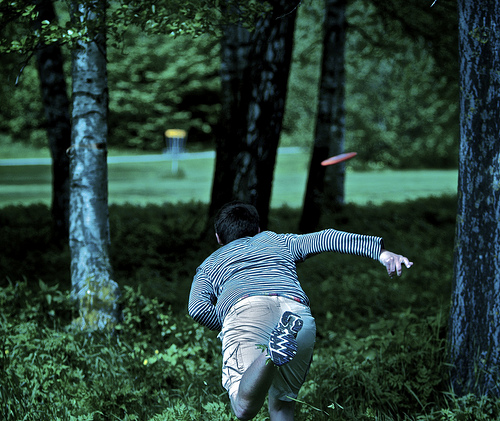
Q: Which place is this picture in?
A: It is at the field.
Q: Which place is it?
A: It is a field.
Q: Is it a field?
A: Yes, it is a field.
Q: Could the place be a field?
A: Yes, it is a field.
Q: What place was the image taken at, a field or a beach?
A: It was taken at a field.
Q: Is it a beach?
A: No, it is a field.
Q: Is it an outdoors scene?
A: Yes, it is outdoors.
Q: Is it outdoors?
A: Yes, it is outdoors.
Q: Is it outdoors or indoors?
A: It is outdoors.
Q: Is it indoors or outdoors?
A: It is outdoors.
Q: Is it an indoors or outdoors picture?
A: It is outdoors.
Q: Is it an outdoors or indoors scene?
A: It is outdoors.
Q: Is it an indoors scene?
A: No, it is outdoors.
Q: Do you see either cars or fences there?
A: No, there are no fences or cars.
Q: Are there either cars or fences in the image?
A: No, there are no fences or cars.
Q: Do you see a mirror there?
A: No, there are no mirrors.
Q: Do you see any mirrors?
A: No, there are no mirrors.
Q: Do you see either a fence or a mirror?
A: No, there are no mirrors or fences.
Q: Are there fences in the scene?
A: No, there are no fences.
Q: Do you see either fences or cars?
A: No, there are no fences or cars.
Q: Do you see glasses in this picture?
A: No, there are no glasses.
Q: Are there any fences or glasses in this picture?
A: No, there are no glasses or fences.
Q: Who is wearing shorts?
A: The man is wearing shorts.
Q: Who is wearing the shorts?
A: The man is wearing shorts.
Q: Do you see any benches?
A: No, there are no benches.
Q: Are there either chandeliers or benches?
A: No, there are no benches or chandeliers.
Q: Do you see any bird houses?
A: No, there are no bird houses.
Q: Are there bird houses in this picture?
A: No, there are no bird houses.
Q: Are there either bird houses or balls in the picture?
A: No, there are no bird houses or balls.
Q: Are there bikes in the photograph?
A: No, there are no bikes.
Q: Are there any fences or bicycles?
A: No, there are no bicycles or fences.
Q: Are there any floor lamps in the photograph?
A: No, there are no floor lamps.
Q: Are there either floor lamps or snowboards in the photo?
A: No, there are no floor lamps or snowboards.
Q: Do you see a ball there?
A: No, there are no balls.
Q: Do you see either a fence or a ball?
A: No, there are no balls or fences.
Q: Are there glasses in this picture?
A: No, there are no glasses.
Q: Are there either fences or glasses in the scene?
A: No, there are no glasses or fences.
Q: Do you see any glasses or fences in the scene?
A: No, there are no glasses or fences.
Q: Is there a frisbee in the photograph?
A: Yes, there is a frisbee.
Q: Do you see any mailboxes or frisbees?
A: Yes, there is a frisbee.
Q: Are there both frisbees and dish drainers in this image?
A: No, there is a frisbee but no dish drainers.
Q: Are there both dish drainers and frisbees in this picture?
A: No, there is a frisbee but no dish drainers.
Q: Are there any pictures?
A: No, there are no pictures.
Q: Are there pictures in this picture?
A: No, there are no pictures.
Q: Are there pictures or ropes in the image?
A: No, there are no pictures or ropes.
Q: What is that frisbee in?
A: The frisbee is in the air.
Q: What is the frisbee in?
A: The frisbee is in the air.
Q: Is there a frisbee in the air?
A: Yes, there is a frisbee in the air.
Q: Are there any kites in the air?
A: No, there is a frisbee in the air.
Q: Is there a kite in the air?
A: No, there is a frisbee in the air.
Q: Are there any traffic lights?
A: No, there are no traffic lights.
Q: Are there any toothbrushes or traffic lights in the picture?
A: No, there are no traffic lights or toothbrushes.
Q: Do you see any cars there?
A: No, there are no cars.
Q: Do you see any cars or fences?
A: No, there are no cars or fences.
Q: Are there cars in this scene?
A: No, there are no cars.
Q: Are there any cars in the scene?
A: No, there are no cars.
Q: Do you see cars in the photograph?
A: No, there are no cars.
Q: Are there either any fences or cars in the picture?
A: No, there are no cars or fences.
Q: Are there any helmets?
A: No, there are no helmets.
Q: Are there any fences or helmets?
A: No, there are no helmets or fences.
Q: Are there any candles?
A: No, there are no candles.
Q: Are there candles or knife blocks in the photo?
A: No, there are no candles or knife blocks.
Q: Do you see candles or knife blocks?
A: No, there are no candles or knife blocks.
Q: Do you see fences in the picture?
A: No, there are no fences.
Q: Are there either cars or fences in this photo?
A: No, there are no fences or cars.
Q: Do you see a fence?
A: No, there are no fences.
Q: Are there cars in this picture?
A: No, there are no cars.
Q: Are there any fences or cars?
A: No, there are no cars or fences.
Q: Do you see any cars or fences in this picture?
A: No, there are no cars or fences.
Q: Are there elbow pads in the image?
A: No, there are no elbow pads.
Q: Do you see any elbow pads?
A: No, there are no elbow pads.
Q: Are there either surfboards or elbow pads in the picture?
A: No, there are no elbow pads or surfboards.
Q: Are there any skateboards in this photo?
A: No, there are no skateboards.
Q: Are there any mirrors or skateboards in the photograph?
A: No, there are no skateboards or mirrors.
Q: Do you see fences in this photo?
A: No, there are no fences.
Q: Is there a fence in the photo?
A: No, there are no fences.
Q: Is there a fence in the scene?
A: No, there are no fences.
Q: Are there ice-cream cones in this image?
A: No, there are no ice-cream cones.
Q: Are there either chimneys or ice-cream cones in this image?
A: No, there are no ice-cream cones or chimneys.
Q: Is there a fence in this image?
A: No, there are no fences.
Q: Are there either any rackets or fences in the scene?
A: No, there are no fences or rackets.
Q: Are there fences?
A: No, there are no fences.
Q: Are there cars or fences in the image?
A: No, there are no fences or cars.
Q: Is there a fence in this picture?
A: No, there are no fences.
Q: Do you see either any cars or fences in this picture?
A: No, there are no fences or cars.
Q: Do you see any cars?
A: No, there are no cars.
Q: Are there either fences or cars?
A: No, there are no cars or fences.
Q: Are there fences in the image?
A: No, there are no fences.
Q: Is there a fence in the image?
A: No, there are no fences.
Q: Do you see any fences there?
A: No, there are no fences.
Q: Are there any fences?
A: No, there are no fences.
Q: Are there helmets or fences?
A: No, there are no fences or helmets.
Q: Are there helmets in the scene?
A: No, there are no helmets.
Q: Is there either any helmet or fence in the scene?
A: No, there are no helmets or fences.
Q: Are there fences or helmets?
A: No, there are no helmets or fences.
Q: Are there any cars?
A: No, there are no cars.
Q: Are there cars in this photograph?
A: No, there are no cars.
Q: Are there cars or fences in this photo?
A: No, there are no cars or fences.